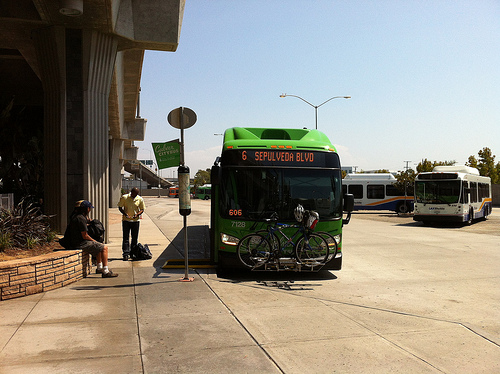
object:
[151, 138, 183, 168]
sign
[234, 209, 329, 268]
bike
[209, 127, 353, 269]
bus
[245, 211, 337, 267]
bikes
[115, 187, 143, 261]
black man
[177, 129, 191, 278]
pole